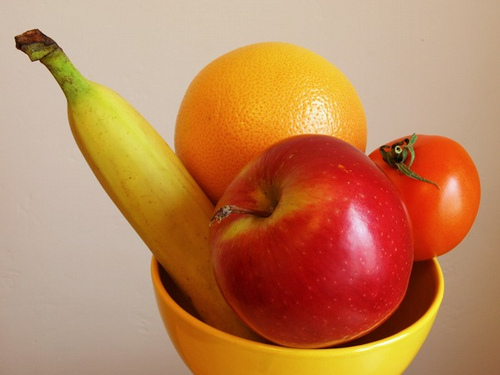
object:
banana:
[15, 28, 263, 341]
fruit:
[174, 42, 369, 207]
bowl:
[150, 257, 445, 374]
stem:
[230, 203, 271, 219]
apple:
[208, 134, 418, 349]